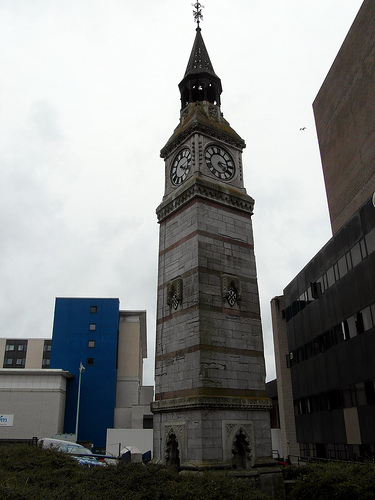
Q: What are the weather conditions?
A: It is cloudy.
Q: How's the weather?
A: It is cloudy.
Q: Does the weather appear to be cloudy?
A: Yes, it is cloudy.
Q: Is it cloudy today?
A: Yes, it is cloudy.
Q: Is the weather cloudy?
A: Yes, it is cloudy.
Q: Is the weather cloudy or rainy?
A: It is cloudy.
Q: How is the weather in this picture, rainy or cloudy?
A: It is cloudy.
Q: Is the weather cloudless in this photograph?
A: No, it is cloudy.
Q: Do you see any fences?
A: No, there are no fences.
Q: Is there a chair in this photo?
A: No, there are no chairs.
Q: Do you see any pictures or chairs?
A: No, there are no chairs or pictures.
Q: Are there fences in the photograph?
A: No, there are no fences.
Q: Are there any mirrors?
A: No, there are no mirrors.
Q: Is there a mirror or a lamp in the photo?
A: No, there are no mirrors or lamps.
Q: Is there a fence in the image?
A: No, there are no fences.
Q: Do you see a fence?
A: No, there are no fences.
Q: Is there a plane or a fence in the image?
A: No, there are no fences or airplanes.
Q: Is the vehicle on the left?
A: Yes, the vehicle is on the left of the image.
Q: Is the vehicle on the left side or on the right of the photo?
A: The vehicle is on the left of the image.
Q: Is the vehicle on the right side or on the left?
A: The vehicle is on the left of the image.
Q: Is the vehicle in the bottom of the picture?
A: Yes, the vehicle is in the bottom of the image.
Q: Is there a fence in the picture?
A: No, there are no fences.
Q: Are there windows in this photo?
A: Yes, there is a window.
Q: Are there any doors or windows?
A: Yes, there is a window.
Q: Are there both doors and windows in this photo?
A: No, there is a window but no doors.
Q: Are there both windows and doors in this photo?
A: No, there is a window but no doors.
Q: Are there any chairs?
A: No, there are no chairs.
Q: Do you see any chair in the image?
A: No, there are no chairs.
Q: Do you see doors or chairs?
A: No, there are no chairs or doors.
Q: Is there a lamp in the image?
A: No, there are no lamps.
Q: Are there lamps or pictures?
A: No, there are no lamps or pictures.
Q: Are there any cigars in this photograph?
A: No, there are no cigars.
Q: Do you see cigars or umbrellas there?
A: No, there are no cigars or umbrellas.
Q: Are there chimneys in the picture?
A: No, there are no chimneys.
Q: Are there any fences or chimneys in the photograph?
A: No, there are no chimneys or fences.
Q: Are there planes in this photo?
A: No, there are no planes.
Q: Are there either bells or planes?
A: No, there are no planes or bells.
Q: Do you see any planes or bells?
A: No, there are no planes or bells.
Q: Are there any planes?
A: No, there are no planes.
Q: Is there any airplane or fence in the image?
A: No, there are no airplanes or fences.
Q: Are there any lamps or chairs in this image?
A: No, there are no lamps or chairs.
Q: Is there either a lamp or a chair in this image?
A: No, there are no lamps or chairs.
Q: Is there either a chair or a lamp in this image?
A: No, there are no lamps or chairs.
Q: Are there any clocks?
A: Yes, there is a clock.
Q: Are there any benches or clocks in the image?
A: Yes, there is a clock.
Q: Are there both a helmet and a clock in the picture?
A: No, there is a clock but no helmets.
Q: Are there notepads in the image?
A: No, there are no notepads.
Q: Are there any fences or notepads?
A: No, there are no notepads or fences.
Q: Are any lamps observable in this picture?
A: No, there are no lamps.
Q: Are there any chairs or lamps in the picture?
A: No, there are no lamps or chairs.